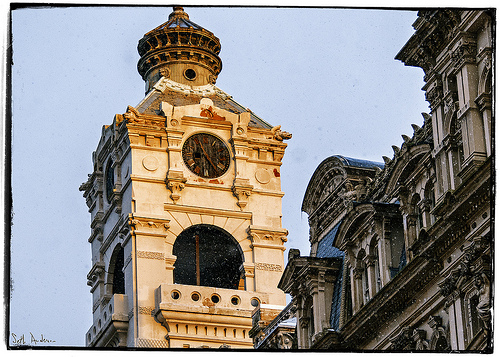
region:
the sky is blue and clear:
[18, 18, 100, 128]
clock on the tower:
[159, 124, 234, 182]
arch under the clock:
[171, 217, 250, 299]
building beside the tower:
[276, 138, 498, 354]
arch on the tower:
[96, 237, 145, 300]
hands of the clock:
[197, 133, 227, 173]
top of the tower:
[136, 18, 231, 82]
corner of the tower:
[127, 188, 163, 249]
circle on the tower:
[139, 151, 159, 175]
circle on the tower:
[253, 164, 275, 185]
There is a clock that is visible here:
[197, 126, 234, 218]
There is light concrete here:
[131, 228, 159, 307]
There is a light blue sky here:
[303, 68, 323, 125]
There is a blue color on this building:
[322, 235, 339, 269]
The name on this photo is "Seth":
[9, 325, 24, 355]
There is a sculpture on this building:
[473, 279, 493, 332]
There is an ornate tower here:
[165, 23, 192, 74]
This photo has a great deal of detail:
[121, 79, 251, 350]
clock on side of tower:
[184, 125, 232, 176]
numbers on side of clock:
[187, 139, 202, 149]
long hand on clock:
[200, 152, 218, 172]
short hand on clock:
[188, 139, 212, 153]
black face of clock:
[184, 143, 224, 175]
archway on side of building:
[165, 209, 252, 286]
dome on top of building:
[128, 18, 215, 65]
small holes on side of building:
[155, 289, 255, 310]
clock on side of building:
[92, 159, 126, 194]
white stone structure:
[131, 182, 162, 210]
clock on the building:
[182, 129, 229, 180]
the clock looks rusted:
[183, 130, 228, 178]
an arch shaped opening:
[174, 223, 246, 288]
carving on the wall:
[167, 169, 185, 199]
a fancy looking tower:
[136, 5, 221, 95]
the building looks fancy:
[246, 10, 491, 351]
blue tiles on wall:
[317, 220, 345, 257]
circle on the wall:
[141, 152, 159, 169]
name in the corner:
[11, 332, 56, 346]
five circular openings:
[171, 288, 261, 305]